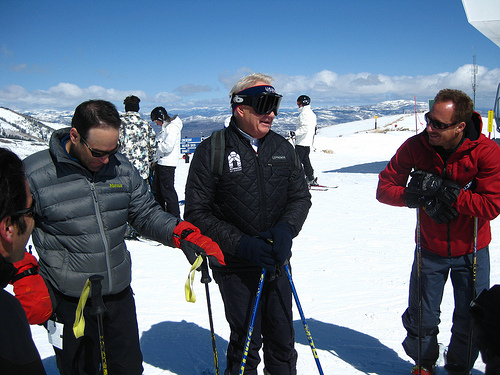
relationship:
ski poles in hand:
[236, 267, 267, 374] [240, 234, 277, 274]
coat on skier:
[183, 116, 312, 270] [16, 57, 183, 352]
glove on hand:
[172, 221, 226, 271] [167, 214, 226, 269]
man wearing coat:
[0, 73, 500, 375] [183, 121, 320, 269]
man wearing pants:
[0, 73, 500, 375] [194, 240, 307, 373]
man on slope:
[0, 73, 500, 375] [16, 110, 483, 358]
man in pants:
[0, 73, 500, 375] [47, 286, 142, 373]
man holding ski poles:
[0, 73, 500, 375] [235, 237, 326, 349]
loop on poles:
[69, 277, 94, 346] [78, 276, 152, 373]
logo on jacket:
[223, 148, 243, 174] [180, 122, 312, 260]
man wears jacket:
[0, 73, 500, 375] [180, 122, 312, 260]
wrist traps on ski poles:
[163, 253, 218, 302] [409, 200, 483, 362]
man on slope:
[0, 73, 500, 375] [324, 139, 363, 202]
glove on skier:
[173, 219, 230, 268] [182, 70, 325, 372]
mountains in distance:
[0, 100, 430, 161] [5, 6, 495, 153]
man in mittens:
[180, 50, 344, 367] [236, 223, 302, 277]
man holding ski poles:
[180, 50, 344, 367] [236, 226, 326, 371]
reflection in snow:
[137, 280, 459, 373] [318, 216, 385, 314]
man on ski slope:
[0, 73, 500, 375] [11, 100, 496, 363]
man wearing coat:
[0, 73, 500, 375] [373, 132, 498, 254]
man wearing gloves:
[0, 73, 500, 375] [395, 152, 485, 224]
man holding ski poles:
[0, 73, 500, 375] [235, 239, 327, 373]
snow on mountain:
[314, 223, 399, 315] [251, 61, 431, 167]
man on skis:
[0, 73, 500, 375] [297, 170, 333, 197]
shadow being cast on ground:
[294, 262, 416, 372] [7, 183, 485, 340]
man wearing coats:
[0, 73, 500, 375] [145, 115, 192, 173]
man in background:
[0, 73, 500, 375] [11, 61, 499, 235]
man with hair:
[0, 73, 500, 375] [226, 67, 275, 92]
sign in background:
[174, 132, 201, 155] [5, 51, 487, 211]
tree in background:
[450, 41, 493, 115] [3, 66, 488, 242]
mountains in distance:
[16, 99, 428, 139] [3, 10, 495, 119]